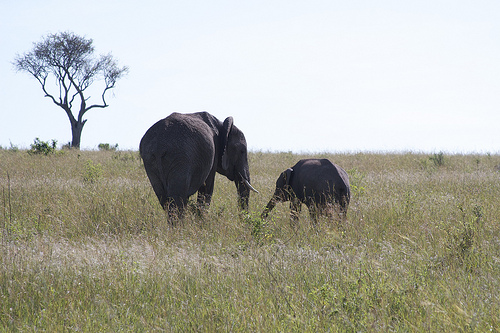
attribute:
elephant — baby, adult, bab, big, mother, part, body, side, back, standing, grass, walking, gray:
[129, 73, 379, 271]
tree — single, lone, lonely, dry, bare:
[25, 26, 136, 161]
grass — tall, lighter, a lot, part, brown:
[72, 227, 131, 307]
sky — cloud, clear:
[264, 1, 358, 69]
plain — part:
[34, 221, 128, 268]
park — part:
[9, 143, 127, 215]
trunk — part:
[229, 167, 261, 219]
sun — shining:
[326, 20, 448, 115]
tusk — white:
[233, 173, 265, 206]